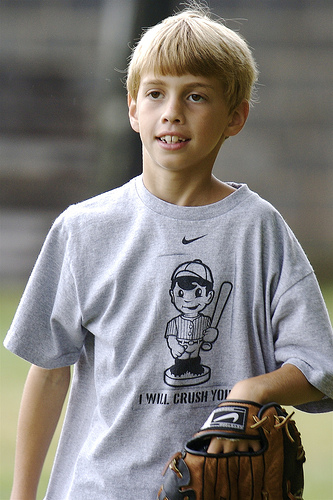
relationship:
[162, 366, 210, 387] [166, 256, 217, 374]
base under child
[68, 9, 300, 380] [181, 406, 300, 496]
young boy with baseball glove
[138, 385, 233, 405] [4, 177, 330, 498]
text on shirt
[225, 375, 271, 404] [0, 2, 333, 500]
wrist on young boy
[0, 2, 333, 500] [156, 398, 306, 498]
young boy wearing baseball glove